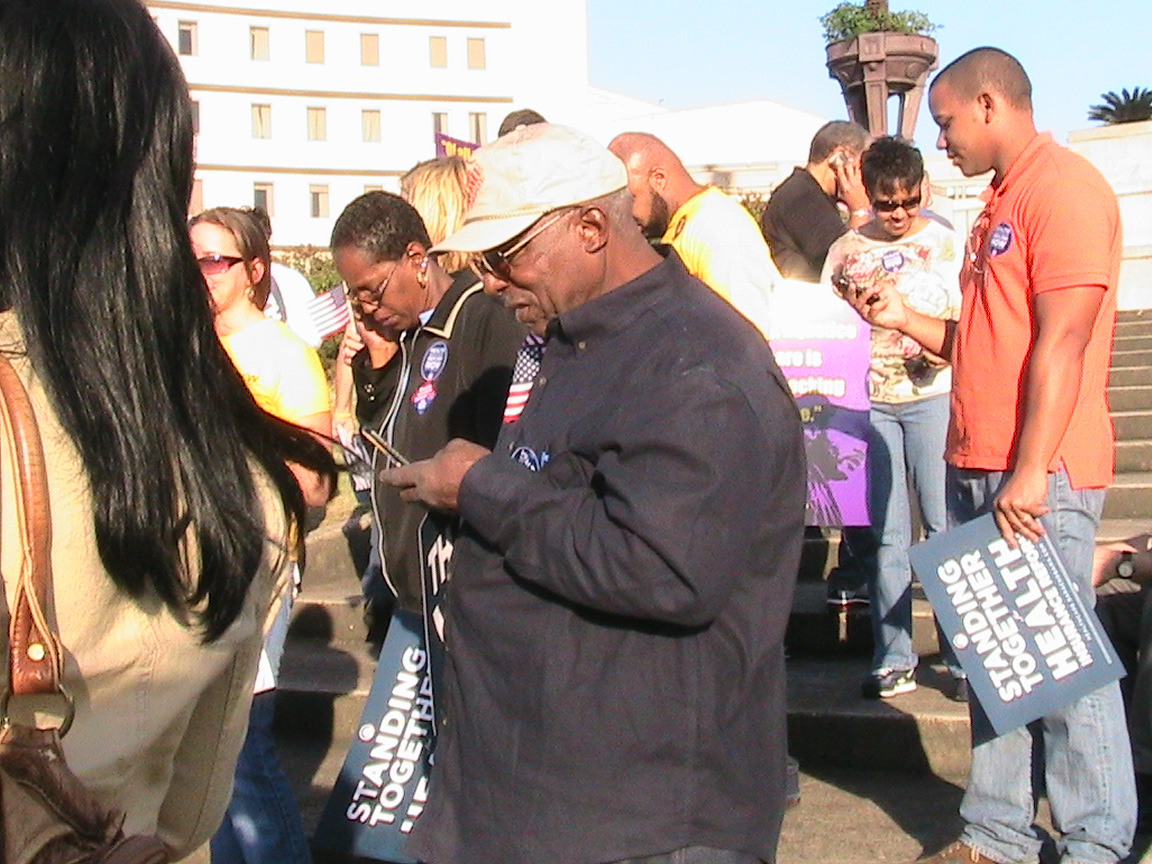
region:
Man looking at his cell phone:
[826, 37, 1143, 854]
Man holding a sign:
[827, 39, 1133, 848]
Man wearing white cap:
[375, 113, 781, 850]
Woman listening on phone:
[332, 187, 527, 606]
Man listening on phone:
[743, 113, 861, 267]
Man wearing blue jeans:
[837, 48, 1141, 856]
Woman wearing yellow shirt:
[164, 199, 335, 505]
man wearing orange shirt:
[838, 48, 1135, 859]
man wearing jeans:
[822, 46, 1151, 860]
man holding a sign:
[838, 50, 1150, 862]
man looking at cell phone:
[356, 125, 803, 862]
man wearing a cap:
[361, 127, 802, 862]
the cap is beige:
[423, 117, 638, 265]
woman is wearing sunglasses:
[818, 135, 984, 707]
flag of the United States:
[297, 280, 364, 352]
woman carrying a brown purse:
[7, 3, 308, 862]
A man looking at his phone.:
[353, 115, 798, 858]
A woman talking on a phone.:
[335, 179, 465, 491]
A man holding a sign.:
[829, 49, 1117, 860]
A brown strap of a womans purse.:
[4, 345, 208, 853]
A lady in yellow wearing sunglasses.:
[177, 210, 330, 422]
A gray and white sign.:
[901, 503, 1118, 735]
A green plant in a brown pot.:
[827, 0, 940, 113]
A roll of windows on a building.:
[192, 27, 494, 64]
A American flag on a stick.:
[309, 269, 351, 346]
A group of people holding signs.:
[11, 48, 1126, 852]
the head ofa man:
[466, 113, 701, 387]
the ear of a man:
[552, 182, 644, 298]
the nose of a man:
[471, 256, 522, 310]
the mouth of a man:
[476, 276, 576, 364]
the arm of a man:
[412, 338, 841, 677]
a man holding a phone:
[323, 325, 604, 594]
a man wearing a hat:
[428, 122, 671, 319]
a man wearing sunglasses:
[436, 157, 663, 318]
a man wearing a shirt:
[353, 116, 910, 825]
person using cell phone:
[357, 121, 811, 860]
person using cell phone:
[823, 41, 1136, 861]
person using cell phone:
[331, 192, 535, 626]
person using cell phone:
[809, 137, 973, 711]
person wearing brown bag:
[2, 3, 372, 860]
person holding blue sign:
[831, 36, 1144, 850]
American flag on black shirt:
[500, 341, 541, 422]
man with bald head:
[610, 130, 774, 375]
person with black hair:
[2, 1, 361, 652]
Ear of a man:
[973, 89, 1002, 131]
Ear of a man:
[570, 201, 616, 263]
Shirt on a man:
[948, 133, 1129, 499]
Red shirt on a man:
[947, 143, 1123, 495]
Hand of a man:
[372, 438, 485, 516]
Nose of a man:
[478, 265, 509, 302]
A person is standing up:
[0, 0, 379, 862]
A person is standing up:
[183, 207, 337, 861]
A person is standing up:
[331, 192, 536, 616]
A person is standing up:
[828, 42, 1139, 861]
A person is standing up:
[818, 134, 971, 700]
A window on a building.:
[250, 27, 269, 61]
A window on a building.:
[306, 29, 325, 65]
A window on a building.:
[359, 32, 380, 68]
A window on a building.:
[250, 103, 273, 142]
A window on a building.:
[178, 16, 201, 58]